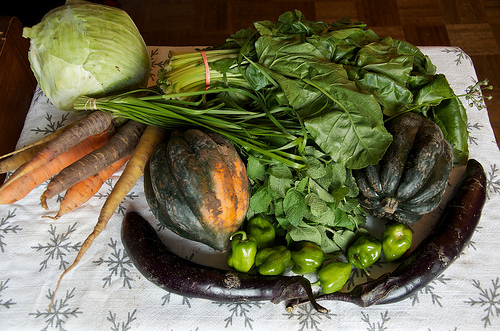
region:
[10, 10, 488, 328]
assortment of vegetables on a sheet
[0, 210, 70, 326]
white linen sheet with a design on it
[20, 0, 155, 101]
a cabbage on a table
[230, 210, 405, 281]
eight green peppers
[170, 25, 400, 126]
leafy green vegetables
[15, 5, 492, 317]
home grown produce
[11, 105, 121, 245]
long sticks of carrots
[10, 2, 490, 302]
vegetables on a tabletop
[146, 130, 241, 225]
over-ripe squash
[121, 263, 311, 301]
long black eggplant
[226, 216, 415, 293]
the green peppers on the towel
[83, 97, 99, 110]
the band on the stock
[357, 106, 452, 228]
the squash on the table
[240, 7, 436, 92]
the lettuce on the table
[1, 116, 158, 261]
the pile of carrots on the table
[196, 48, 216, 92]
the red reubberband on the stock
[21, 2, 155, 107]
the head of lettuce on the table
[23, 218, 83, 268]
the snowflake on the towel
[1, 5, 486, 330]
the veggies on the towel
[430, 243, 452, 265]
the scars on the vegetable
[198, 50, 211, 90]
red rubber band on top of a spinach bunch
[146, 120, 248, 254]
acorn squash on top of a table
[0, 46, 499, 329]
white table cloth on top of a table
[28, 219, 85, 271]
gray snowflake printed on tablecloth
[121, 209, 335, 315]
eggplant on top of a table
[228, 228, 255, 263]
bonnet pepper next to eggplant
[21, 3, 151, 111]
round cabbage next to carrot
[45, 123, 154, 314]
long orange carrot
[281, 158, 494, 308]
eggplant on top of tablecloth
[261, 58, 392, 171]
a green leaf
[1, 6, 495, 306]
Vegetables on the cloth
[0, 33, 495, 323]
The cloth is white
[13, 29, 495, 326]
The snow flakes are silver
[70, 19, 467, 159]
Green leaves on the cloth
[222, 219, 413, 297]
The peppers are green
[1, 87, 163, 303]
The carrots are orange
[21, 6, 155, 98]
The cabbage is light green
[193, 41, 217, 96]
Pink band around vegetables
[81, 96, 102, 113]
Beige band tied around stems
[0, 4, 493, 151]
The floor is wood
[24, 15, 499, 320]
vegetables on the table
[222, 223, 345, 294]
the peppers are green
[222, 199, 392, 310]
the peppers are green